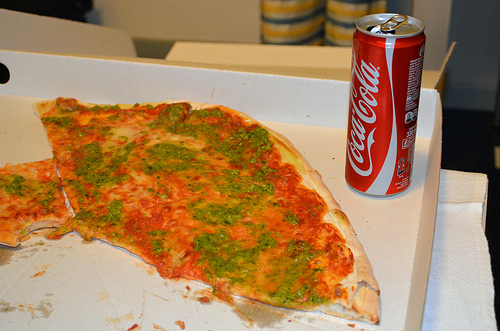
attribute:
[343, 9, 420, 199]
can — red, white, shiny, tall, opened, long, skinny, large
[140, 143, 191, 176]
herbs — green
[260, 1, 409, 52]
fabric — blue, yellow, white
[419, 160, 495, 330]
towel — white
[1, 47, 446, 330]
box — white, open, large, cardboard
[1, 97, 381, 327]
pizza — cooked, partially eaten, slice, partial, large, half eaten, ready